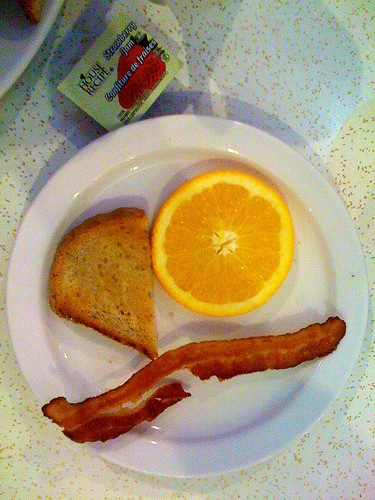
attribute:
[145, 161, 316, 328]
orange — yellow, ripe, sliced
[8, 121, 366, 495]
plate — white, round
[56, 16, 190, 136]
jam — packaged, square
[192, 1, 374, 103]
table — white, tiled, ceramic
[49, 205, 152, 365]
toast — sliced, buttered, triangle, brown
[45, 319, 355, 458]
bacon — beef, half-eaten